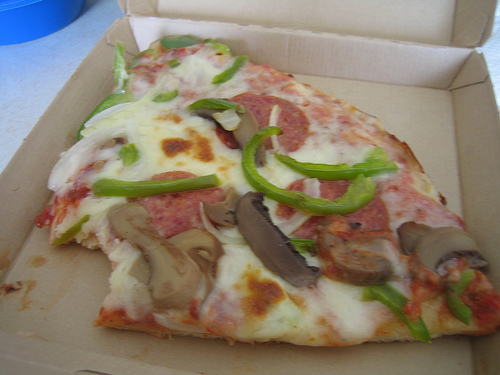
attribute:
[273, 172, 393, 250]
pepperoni — sliced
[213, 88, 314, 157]
pepperoni — sliced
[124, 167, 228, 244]
pepperoni — sliced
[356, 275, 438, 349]
peppers — green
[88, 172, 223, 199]
peppers — green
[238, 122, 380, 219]
peppers — green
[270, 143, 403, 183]
peppers — green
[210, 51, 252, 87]
peppers — green